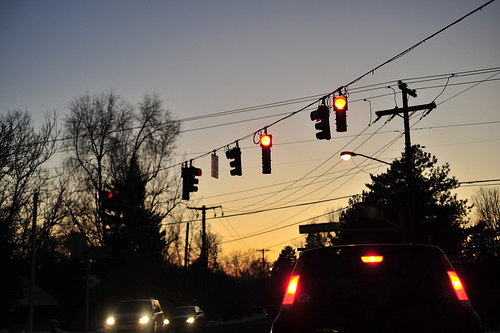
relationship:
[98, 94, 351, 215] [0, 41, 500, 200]
lights are on wire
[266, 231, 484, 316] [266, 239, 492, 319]
brakelights are on suv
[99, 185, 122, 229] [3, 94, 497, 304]
red light hidden by trees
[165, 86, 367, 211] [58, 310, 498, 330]
traffic lights hanging above street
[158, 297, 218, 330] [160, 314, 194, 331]
car has head lights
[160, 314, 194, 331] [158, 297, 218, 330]
head lights on car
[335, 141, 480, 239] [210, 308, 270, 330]
tree lining road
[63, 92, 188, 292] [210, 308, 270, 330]
tree lining road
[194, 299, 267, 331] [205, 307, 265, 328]
snow on road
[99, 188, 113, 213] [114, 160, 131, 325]
light on pole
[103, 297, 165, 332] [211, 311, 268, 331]
car on street